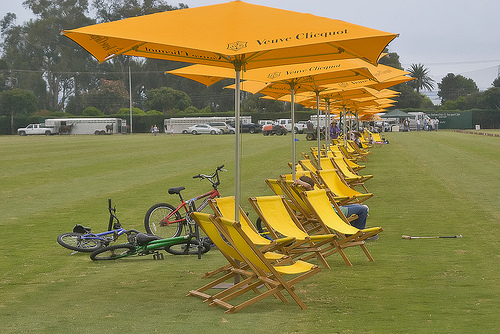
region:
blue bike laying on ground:
[34, 190, 129, 264]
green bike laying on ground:
[96, 210, 196, 290]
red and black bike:
[151, 154, 252, 224]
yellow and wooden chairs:
[203, 191, 294, 327]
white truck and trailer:
[0, 95, 133, 143]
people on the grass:
[121, 108, 161, 171]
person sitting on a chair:
[250, 172, 391, 251]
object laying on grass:
[390, 203, 465, 289]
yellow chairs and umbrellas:
[151, 2, 421, 309]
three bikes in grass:
[48, 74, 278, 301]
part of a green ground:
[405, 277, 433, 312]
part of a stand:
[269, 264, 299, 317]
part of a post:
[220, 140, 247, 206]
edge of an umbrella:
[246, 38, 323, 69]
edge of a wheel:
[141, 201, 165, 224]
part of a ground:
[413, 246, 458, 295]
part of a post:
[228, 170, 243, 228]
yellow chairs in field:
[208, 159, 375, 271]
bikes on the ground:
[53, 216, 155, 286]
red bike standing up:
[150, 138, 240, 228]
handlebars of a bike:
[188, 152, 238, 198]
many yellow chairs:
[228, 116, 390, 300]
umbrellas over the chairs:
[168, 6, 310, 70]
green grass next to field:
[378, 140, 466, 203]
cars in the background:
[20, 108, 224, 150]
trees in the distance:
[1, 23, 71, 88]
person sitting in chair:
[299, 171, 379, 225]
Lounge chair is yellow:
[205, 214, 348, 315]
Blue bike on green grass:
[55, 197, 151, 252]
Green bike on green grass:
[87, 221, 228, 260]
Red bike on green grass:
[143, 162, 227, 240]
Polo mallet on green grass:
[397, 227, 467, 243]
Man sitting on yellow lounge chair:
[294, 172, 378, 239]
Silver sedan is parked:
[187, 121, 224, 136]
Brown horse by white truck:
[57, 117, 77, 134]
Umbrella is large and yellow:
[57, 0, 403, 302]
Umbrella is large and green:
[382, 105, 415, 136]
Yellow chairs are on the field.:
[203, 195, 364, 292]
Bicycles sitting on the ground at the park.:
[85, 189, 197, 254]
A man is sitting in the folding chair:
[293, 172, 378, 229]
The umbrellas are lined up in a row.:
[64, 11, 400, 128]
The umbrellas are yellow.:
[86, 13, 400, 85]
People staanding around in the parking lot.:
[322, 113, 414, 132]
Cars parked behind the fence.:
[183, 108, 258, 134]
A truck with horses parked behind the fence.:
[22, 118, 62, 143]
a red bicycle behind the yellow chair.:
[125, 166, 244, 238]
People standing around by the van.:
[402, 105, 458, 135]